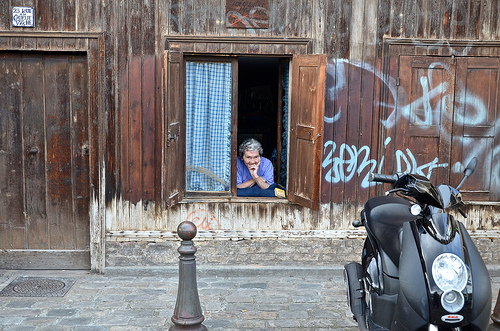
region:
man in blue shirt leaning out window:
[234, 133, 279, 195]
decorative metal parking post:
[165, 215, 212, 326]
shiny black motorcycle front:
[337, 165, 497, 327]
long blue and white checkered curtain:
[180, 55, 235, 195]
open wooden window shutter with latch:
[285, 46, 325, 206]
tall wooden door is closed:
[0, 25, 106, 272]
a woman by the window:
[231, 136, 286, 201]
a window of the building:
[153, 33, 328, 216]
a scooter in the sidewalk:
[340, 153, 498, 328]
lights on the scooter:
[429, 251, 471, 316]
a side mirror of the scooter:
[460, 156, 480, 181]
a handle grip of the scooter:
[364, 170, 400, 188]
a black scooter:
[337, 154, 499, 329]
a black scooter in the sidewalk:
[341, 154, 495, 329]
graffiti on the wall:
[323, 52, 498, 194]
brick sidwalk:
[77, 267, 350, 329]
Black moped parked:
[345, 169, 492, 329]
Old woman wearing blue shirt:
[233, 135, 275, 195]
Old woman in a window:
[235, 137, 278, 195]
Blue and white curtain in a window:
[183, 55, 236, 197]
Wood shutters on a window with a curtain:
[160, 35, 325, 212]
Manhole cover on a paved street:
[2, 273, 76, 300]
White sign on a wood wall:
[6, 2, 38, 29]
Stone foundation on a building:
[100, 231, 498, 272]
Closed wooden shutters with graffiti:
[391, 54, 498, 204]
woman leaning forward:
[228, 136, 272, 194]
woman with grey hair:
[231, 134, 274, 191]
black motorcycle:
[340, 166, 492, 329]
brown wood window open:
[162, 30, 327, 212]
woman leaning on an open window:
[155, 36, 325, 213]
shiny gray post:
[165, 220, 215, 328]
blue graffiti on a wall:
[322, 134, 448, 187]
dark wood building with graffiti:
[0, 0, 499, 270]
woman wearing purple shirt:
[232, 138, 274, 193]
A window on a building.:
[160, 45, 304, 231]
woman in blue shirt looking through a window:
[233, 136, 275, 195]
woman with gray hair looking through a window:
[237, 137, 276, 192]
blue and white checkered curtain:
[183, 58, 233, 200]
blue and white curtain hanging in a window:
[183, 53, 236, 200]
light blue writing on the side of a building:
[321, 57, 498, 192]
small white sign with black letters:
[9, 5, 36, 30]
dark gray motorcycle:
[345, 155, 495, 328]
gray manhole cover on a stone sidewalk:
[0, 271, 80, 298]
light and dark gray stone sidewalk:
[3, 264, 499, 328]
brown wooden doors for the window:
[158, 31, 326, 216]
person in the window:
[206, 107, 296, 193]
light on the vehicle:
[403, 225, 482, 306]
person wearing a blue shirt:
[210, 130, 297, 194]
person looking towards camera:
[173, 118, 295, 245]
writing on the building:
[298, 127, 404, 206]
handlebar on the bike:
[336, 145, 422, 214]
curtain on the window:
[146, 71, 248, 203]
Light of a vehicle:
[430, 283, 470, 315]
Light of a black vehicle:
[434, 286, 466, 315]